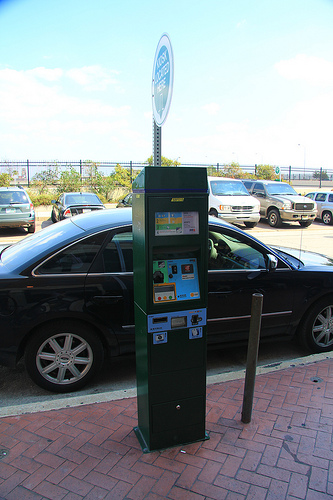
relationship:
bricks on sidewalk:
[237, 450, 261, 471] [2, 350, 331, 497]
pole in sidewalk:
[240, 293, 264, 423] [2, 350, 331, 497]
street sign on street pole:
[150, 31, 173, 129] [153, 110, 162, 164]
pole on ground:
[241, 292, 261, 422] [243, 430, 304, 470]